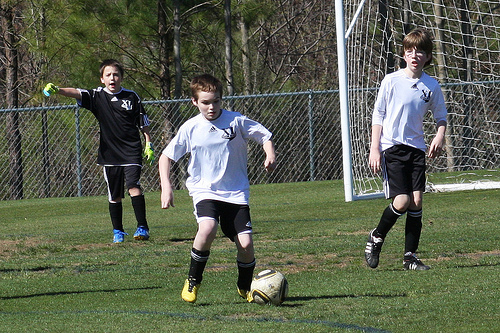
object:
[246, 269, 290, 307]
ball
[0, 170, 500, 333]
field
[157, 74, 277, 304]
boy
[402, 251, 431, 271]
sneakers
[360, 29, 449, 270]
kids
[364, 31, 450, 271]
boy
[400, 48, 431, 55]
glasses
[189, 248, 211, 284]
socks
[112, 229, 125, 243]
shoes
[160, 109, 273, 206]
shirt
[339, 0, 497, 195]
net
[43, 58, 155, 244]
boy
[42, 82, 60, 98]
gloves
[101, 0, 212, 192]
trees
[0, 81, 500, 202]
fence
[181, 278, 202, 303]
shoes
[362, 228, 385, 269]
shoes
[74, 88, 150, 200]
uniform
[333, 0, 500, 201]
goal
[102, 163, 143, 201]
shorts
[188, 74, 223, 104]
hair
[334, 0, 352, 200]
post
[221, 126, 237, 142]
logo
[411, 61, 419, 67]
mouth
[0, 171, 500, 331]
grass